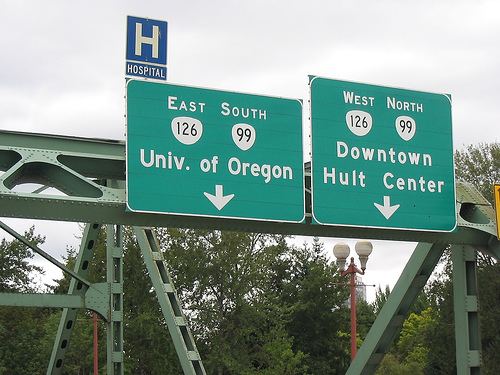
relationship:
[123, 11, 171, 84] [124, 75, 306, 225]
hospital sign above freeway sign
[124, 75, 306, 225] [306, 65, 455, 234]
freeway sign beside freeway sign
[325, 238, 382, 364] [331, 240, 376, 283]
lamp post has dual lamps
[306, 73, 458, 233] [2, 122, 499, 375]
freeway sign fastened to trestle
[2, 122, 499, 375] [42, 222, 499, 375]
trestle supported by bents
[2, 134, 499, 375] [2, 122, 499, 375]
trees behind trestle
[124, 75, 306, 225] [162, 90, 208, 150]
freeway sign for route 126 east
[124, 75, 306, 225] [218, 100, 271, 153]
freeway sign for route 99 south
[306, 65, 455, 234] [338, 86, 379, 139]
freeway sign for route 126 west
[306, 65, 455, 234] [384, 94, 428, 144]
freeway sign for route 99 north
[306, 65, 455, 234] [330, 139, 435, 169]
freeway sign for downtown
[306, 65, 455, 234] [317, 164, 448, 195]
freeway sign for hult center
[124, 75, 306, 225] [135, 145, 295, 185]
freeway sign for university of oregon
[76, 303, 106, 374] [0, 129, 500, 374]
lamp post behind trestle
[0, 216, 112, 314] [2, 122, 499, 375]
sway brace of trestle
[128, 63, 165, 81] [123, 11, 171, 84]
word 'hospital' on hospital sign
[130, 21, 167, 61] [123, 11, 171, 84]
capital letter 'h' of hospital sign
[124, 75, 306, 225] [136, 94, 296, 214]
freeway sign has white lettering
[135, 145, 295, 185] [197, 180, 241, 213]
university of oregon has straight ahead arrow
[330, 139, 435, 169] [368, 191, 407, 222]
downtown indicated by straight ahead arrow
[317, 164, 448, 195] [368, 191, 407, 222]
hult center indicated by straight ahead arrow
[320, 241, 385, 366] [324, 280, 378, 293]
street lamp has cross-bar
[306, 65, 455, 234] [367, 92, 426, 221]
freeway sign for route 99 north exit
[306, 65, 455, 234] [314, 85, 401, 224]
freeway sign to route 126 west exit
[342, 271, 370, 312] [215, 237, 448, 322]
building in far distance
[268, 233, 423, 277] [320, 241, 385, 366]
cloud behind street lamp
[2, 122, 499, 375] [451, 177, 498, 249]
trestle has corner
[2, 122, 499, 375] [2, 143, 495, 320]
trestle has many bolts